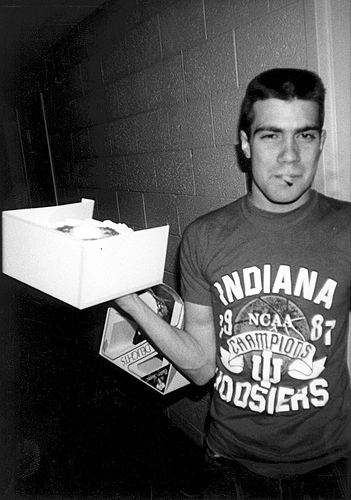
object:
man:
[114, 66, 351, 500]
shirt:
[179, 189, 351, 474]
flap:
[54, 196, 181, 294]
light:
[71, 217, 103, 240]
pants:
[208, 457, 351, 500]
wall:
[13, 0, 338, 225]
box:
[1, 196, 171, 311]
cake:
[49, 216, 135, 240]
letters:
[214, 264, 338, 310]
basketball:
[232, 293, 308, 385]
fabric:
[211, 262, 338, 416]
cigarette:
[283, 174, 295, 183]